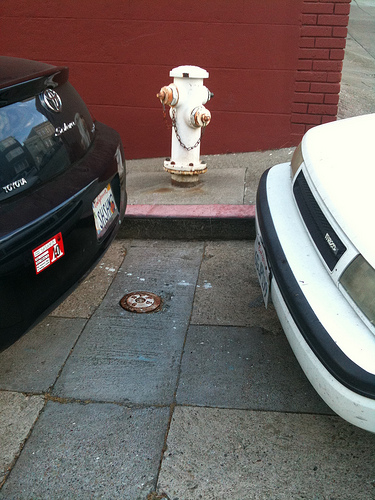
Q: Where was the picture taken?
A: It was taken at the road.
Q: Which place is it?
A: It is a road.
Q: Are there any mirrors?
A: No, there are no mirrors.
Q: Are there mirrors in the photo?
A: No, there are no mirrors.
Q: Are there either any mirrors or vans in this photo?
A: No, there are no mirrors or vans.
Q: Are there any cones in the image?
A: No, there are no cones.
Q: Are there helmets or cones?
A: No, there are no cones or helmets.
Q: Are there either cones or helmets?
A: No, there are no cones or helmets.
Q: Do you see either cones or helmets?
A: No, there are no cones or helmets.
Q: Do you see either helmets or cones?
A: No, there are no cones or helmets.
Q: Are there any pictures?
A: No, there are no pictures.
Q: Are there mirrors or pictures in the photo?
A: No, there are no pictures or mirrors.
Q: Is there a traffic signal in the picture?
A: No, there are no traffic lights.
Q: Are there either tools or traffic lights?
A: No, there are no traffic lights or tools.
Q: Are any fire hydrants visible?
A: Yes, there is a fire hydrant.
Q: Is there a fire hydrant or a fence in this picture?
A: Yes, there is a fire hydrant.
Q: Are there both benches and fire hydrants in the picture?
A: No, there is a fire hydrant but no benches.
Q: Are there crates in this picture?
A: No, there are no crates.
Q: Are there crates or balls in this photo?
A: No, there are no crates or balls.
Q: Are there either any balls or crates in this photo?
A: No, there are no crates or balls.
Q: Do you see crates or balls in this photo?
A: No, there are no crates or balls.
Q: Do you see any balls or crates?
A: No, there are no crates or balls.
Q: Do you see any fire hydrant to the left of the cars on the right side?
A: Yes, there is a fire hydrant to the left of the cars.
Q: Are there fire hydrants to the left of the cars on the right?
A: Yes, there is a fire hydrant to the left of the cars.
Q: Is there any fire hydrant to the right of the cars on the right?
A: No, the fire hydrant is to the left of the cars.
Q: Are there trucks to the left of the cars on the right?
A: No, there is a fire hydrant to the left of the cars.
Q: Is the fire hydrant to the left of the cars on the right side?
A: Yes, the fire hydrant is to the left of the cars.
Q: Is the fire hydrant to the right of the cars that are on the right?
A: No, the fire hydrant is to the left of the cars.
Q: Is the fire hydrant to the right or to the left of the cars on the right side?
A: The fire hydrant is to the left of the cars.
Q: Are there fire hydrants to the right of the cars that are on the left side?
A: Yes, there is a fire hydrant to the right of the cars.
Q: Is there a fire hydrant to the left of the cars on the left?
A: No, the fire hydrant is to the right of the cars.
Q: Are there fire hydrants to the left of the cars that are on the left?
A: No, the fire hydrant is to the right of the cars.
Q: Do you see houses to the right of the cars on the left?
A: No, there is a fire hydrant to the right of the cars.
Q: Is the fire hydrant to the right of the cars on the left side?
A: Yes, the fire hydrant is to the right of the cars.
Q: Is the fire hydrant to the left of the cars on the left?
A: No, the fire hydrant is to the right of the cars.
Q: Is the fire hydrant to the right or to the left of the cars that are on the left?
A: The fire hydrant is to the right of the cars.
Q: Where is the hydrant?
A: The hydrant is on the sidewalk.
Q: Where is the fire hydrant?
A: The hydrant is on the sidewalk.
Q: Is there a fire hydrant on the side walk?
A: Yes, there is a fire hydrant on the side walk.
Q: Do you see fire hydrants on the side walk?
A: Yes, there is a fire hydrant on the side walk.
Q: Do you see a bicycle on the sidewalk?
A: No, there is a fire hydrant on the sidewalk.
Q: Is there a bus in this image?
A: No, there are no buses.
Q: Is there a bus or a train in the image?
A: No, there are no buses or trains.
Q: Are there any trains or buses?
A: No, there are no buses or trains.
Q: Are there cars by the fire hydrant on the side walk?
A: Yes, there are cars by the hydrant.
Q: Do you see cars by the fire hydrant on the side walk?
A: Yes, there are cars by the hydrant.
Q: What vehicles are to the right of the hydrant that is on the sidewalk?
A: The vehicles are cars.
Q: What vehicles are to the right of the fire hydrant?
A: The vehicles are cars.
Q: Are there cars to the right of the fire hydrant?
A: Yes, there are cars to the right of the fire hydrant.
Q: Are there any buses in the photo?
A: No, there are no buses.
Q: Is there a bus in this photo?
A: No, there are no buses.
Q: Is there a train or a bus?
A: No, there are no buses or trains.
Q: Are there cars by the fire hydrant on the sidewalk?
A: Yes, there are cars by the fire hydrant.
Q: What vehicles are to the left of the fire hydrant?
A: The vehicles are cars.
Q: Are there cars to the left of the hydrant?
A: Yes, there are cars to the left of the hydrant.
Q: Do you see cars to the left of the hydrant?
A: Yes, there are cars to the left of the hydrant.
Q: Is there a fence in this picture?
A: No, there are no fences.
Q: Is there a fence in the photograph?
A: No, there are no fences.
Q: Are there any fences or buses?
A: No, there are no fences or buses.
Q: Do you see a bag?
A: No, there are no bags.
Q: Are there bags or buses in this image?
A: No, there are no bags or buses.